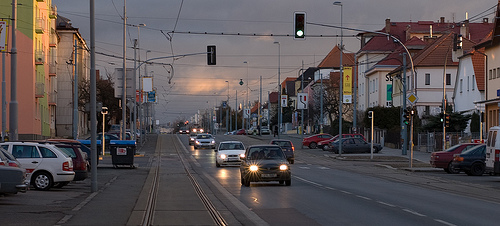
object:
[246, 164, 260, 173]
headlights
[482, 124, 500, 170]
van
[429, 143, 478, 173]
car parked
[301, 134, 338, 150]
car parked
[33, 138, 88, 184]
car parked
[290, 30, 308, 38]
green light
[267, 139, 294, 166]
cars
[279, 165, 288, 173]
headlights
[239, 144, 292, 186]
car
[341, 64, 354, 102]
sign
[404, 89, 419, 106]
sign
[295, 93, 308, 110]
sign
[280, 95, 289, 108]
sign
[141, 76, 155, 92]
sign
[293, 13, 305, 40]
traffic signal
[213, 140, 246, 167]
car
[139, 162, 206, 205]
street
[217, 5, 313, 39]
sky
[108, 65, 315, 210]
urban area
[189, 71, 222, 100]
cloud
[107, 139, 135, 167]
bin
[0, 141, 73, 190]
car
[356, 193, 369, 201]
line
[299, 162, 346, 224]
street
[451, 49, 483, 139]
house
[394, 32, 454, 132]
house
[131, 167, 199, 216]
tracks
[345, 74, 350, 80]
arrow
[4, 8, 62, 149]
building front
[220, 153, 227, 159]
headlight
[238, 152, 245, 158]
headlight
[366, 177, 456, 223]
street